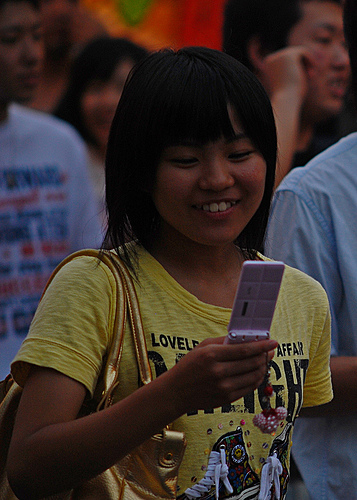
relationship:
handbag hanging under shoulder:
[0, 248, 187, 499] [61, 239, 156, 301]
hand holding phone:
[169, 336, 278, 411] [224, 261, 287, 343]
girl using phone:
[11, 44, 335, 499] [224, 261, 287, 343]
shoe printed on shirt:
[175, 431, 259, 500] [9, 239, 335, 500]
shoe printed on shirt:
[257, 422, 291, 500] [9, 239, 335, 500]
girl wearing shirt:
[11, 44, 335, 499] [9, 239, 335, 500]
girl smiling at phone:
[11, 44, 335, 499] [224, 261, 287, 343]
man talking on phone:
[225, 0, 351, 198] [242, 19, 286, 58]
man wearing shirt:
[2, 1, 109, 381] [2, 102, 102, 380]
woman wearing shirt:
[53, 36, 152, 249] [90, 155, 135, 248]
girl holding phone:
[11, 44, 335, 499] [224, 261, 287, 343]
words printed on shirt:
[148, 332, 308, 422] [9, 239, 335, 500]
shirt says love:
[9, 239, 335, 500] [151, 333, 187, 349]